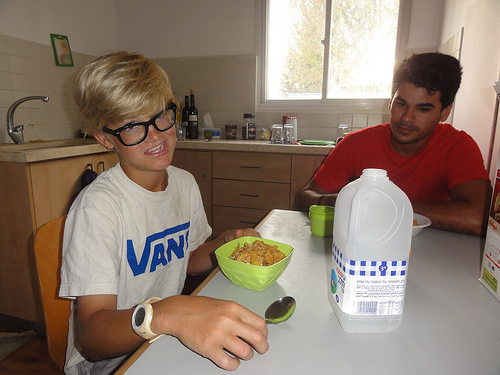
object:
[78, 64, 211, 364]
boy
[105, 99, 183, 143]
glasses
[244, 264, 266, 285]
bowl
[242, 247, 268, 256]
cereal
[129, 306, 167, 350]
watch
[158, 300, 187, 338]
wrist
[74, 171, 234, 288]
shirt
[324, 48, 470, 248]
man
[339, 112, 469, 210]
shirt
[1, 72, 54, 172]
faucet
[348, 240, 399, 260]
milk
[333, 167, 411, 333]
carton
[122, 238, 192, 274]
letters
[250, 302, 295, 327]
spoon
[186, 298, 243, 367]
right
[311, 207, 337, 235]
cup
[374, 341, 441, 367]
table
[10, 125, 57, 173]
sink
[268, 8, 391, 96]
window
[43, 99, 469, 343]
kitchen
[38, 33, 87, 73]
picture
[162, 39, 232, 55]
wall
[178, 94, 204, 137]
bottles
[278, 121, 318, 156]
glasses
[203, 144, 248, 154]
counter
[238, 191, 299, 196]
handle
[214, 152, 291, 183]
cabinets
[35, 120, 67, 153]
water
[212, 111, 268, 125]
jars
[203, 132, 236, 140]
box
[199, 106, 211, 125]
tissues